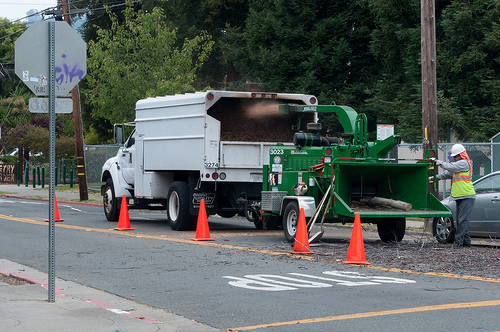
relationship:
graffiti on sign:
[54, 53, 85, 85] [13, 38, 94, 116]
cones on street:
[295, 198, 372, 276] [105, 225, 369, 331]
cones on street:
[189, 194, 376, 269] [107, 222, 281, 326]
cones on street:
[49, 188, 373, 279] [119, 217, 319, 326]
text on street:
[221, 271, 415, 292] [227, 247, 403, 314]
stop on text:
[222, 262, 417, 294] [224, 258, 444, 304]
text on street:
[224, 258, 444, 304] [1, 195, 499, 330]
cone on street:
[343, 210, 370, 262] [72, 219, 429, 330]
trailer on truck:
[258, 101, 462, 243] [230, 64, 475, 292]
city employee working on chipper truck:
[436, 141, 476, 248] [266, 97, 458, 252]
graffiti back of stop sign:
[51, 50, 82, 88] [14, 19, 89, 109]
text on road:
[221, 271, 415, 292] [2, 195, 499, 329]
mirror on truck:
[95, 119, 124, 157] [97, 81, 324, 230]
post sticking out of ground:
[40, 164, 47, 194] [11, 166, 483, 326]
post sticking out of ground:
[23, 160, 30, 186] [11, 166, 483, 326]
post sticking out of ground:
[29, 165, 38, 190] [11, 166, 483, 326]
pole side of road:
[409, 72, 431, 104] [5, 192, 480, 323]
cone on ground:
[341, 212, 370, 264] [17, 187, 477, 314]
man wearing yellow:
[429, 143, 477, 248] [447, 166, 477, 199]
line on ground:
[229, 289, 309, 330] [20, 196, 484, 316]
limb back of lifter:
[371, 194, 411, 214] [329, 155, 452, 220]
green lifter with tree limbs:
[247, 99, 449, 240] [344, 175, 418, 210]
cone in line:
[341, 212, 370, 264] [42, 192, 372, 267]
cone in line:
[289, 207, 313, 252] [42, 192, 372, 267]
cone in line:
[195, 196, 215, 239] [42, 192, 372, 267]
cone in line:
[115, 192, 132, 232] [42, 192, 372, 267]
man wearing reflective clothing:
[429, 142, 476, 244] [449, 157, 476, 199]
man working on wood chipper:
[429, 143, 477, 248] [258, 100, 455, 242]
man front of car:
[429, 143, 477, 248] [430, 175, 484, 246]